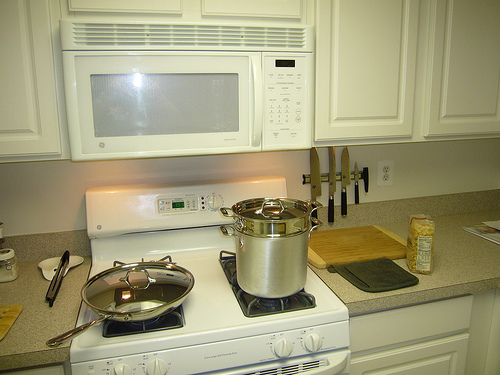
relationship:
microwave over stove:
[59, 17, 315, 162] [69, 174, 351, 375]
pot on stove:
[220, 197, 322, 237] [69, 174, 351, 375]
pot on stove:
[219, 218, 323, 300] [69, 174, 351, 375]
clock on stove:
[171, 202, 184, 209] [69, 174, 351, 375]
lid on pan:
[85, 265, 191, 311] [47, 262, 195, 347]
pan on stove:
[47, 262, 195, 347] [69, 174, 351, 375]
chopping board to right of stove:
[308, 225, 409, 269] [69, 174, 351, 375]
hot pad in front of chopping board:
[326, 258, 418, 293] [308, 225, 409, 269]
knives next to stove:
[305, 142, 325, 234] [69, 174, 351, 375]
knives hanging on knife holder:
[310, 148, 360, 231] [301, 166, 368, 193]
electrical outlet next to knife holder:
[378, 159, 394, 187] [301, 166, 368, 193]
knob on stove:
[304, 334, 322, 353] [69, 174, 351, 375]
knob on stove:
[274, 338, 293, 361] [69, 174, 351, 375]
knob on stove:
[145, 358, 168, 375] [69, 174, 351, 375]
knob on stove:
[114, 363, 136, 375] [69, 174, 351, 375]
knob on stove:
[208, 195, 223, 210] [69, 174, 351, 375]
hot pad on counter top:
[326, 258, 418, 293] [1, 208, 499, 371]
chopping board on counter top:
[308, 225, 409, 269] [1, 208, 499, 371]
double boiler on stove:
[220, 198, 322, 298] [69, 174, 351, 375]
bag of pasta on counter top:
[405, 213, 434, 274] [1, 208, 499, 371]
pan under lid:
[47, 262, 195, 347] [85, 265, 191, 311]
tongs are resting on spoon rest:
[45, 251, 70, 307] [38, 256, 84, 281]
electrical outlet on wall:
[378, 159, 394, 187] [1, 138, 500, 236]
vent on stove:
[241, 359, 327, 374] [69, 174, 351, 375]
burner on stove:
[219, 250, 317, 318] [69, 174, 351, 375]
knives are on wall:
[310, 148, 360, 231] [1, 138, 500, 236]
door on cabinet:
[0, 0, 63, 159] [1, 0, 73, 164]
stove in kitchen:
[69, 174, 351, 375] [1, 0, 499, 374]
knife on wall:
[354, 161, 359, 203] [1, 138, 500, 236]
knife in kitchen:
[340, 145, 350, 216] [1, 0, 499, 374]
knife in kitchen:
[328, 148, 336, 222] [1, 0, 499, 374]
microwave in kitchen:
[59, 17, 315, 162] [1, 0, 499, 374]